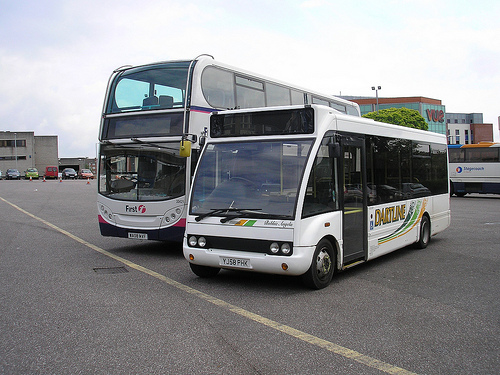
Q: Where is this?
A: This is at the parking lot.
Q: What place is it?
A: It is a parking lot.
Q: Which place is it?
A: It is a parking lot.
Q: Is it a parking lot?
A: Yes, it is a parking lot.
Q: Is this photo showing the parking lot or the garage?
A: It is showing the parking lot.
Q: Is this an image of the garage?
A: No, the picture is showing the parking lot.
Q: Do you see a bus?
A: Yes, there is a bus.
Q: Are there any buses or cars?
A: Yes, there is a bus.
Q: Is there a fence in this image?
A: No, there are no fences.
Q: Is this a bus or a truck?
A: This is a bus.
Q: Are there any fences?
A: No, there are no fences.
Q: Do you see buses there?
A: Yes, there is a bus.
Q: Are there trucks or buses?
A: Yes, there is a bus.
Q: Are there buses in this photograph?
A: Yes, there is a bus.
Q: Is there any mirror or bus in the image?
A: Yes, there is a bus.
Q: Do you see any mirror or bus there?
A: Yes, there is a bus.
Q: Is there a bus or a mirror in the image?
A: Yes, there is a bus.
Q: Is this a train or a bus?
A: This is a bus.